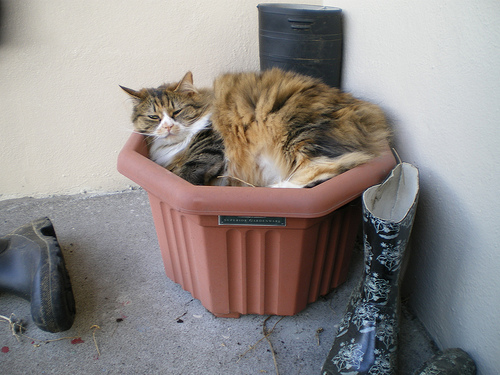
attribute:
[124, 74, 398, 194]
cat — laying, large, striped, resting, big, brown, black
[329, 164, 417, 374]
boot — black, white, floral, rubber, patterned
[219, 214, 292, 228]
label — small, mounted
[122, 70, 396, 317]
holder — large, orange, red, rust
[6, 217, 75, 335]
boot — black, dirty, plain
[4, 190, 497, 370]
ground — gray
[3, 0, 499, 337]
wall — tan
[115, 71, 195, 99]
ears — pointy, pointed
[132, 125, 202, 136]
whiskers — white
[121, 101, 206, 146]
face — gray, white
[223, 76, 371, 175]
fur — long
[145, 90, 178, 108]
stripes — black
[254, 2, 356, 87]
boot — black